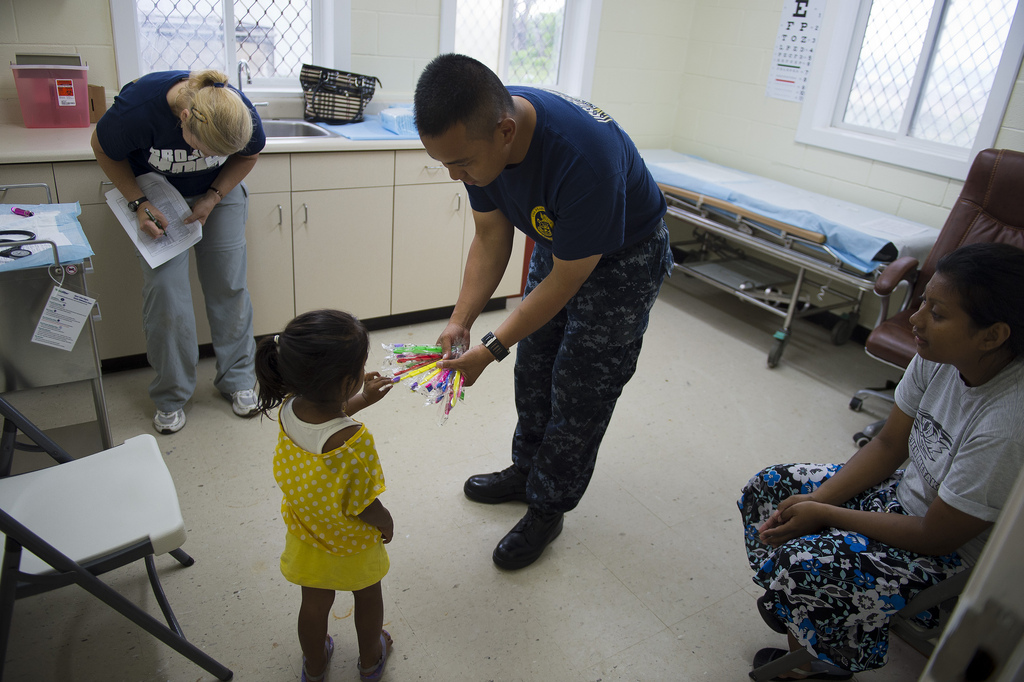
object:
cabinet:
[290, 150, 396, 320]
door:
[291, 186, 393, 321]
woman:
[91, 69, 267, 434]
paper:
[104, 172, 202, 270]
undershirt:
[280, 395, 362, 454]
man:
[413, 52, 675, 569]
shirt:
[463, 85, 666, 261]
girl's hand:
[364, 370, 394, 404]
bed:
[638, 148, 940, 367]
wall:
[591, 0, 1024, 346]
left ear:
[498, 118, 518, 144]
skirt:
[280, 530, 390, 591]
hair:
[172, 70, 257, 158]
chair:
[0, 395, 235, 681]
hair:
[247, 310, 370, 429]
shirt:
[273, 396, 386, 555]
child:
[249, 310, 396, 682]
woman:
[736, 242, 1024, 682]